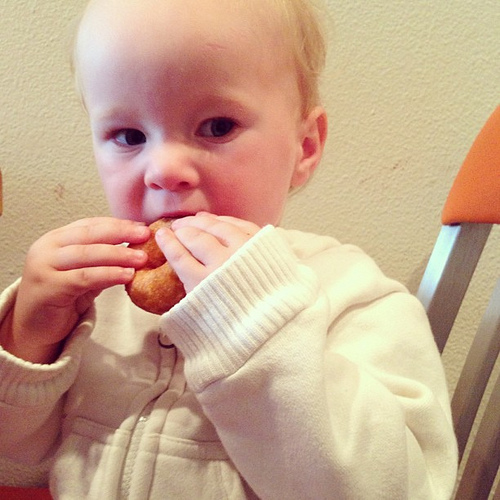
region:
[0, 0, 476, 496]
Baby eating a donut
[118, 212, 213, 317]
Donut is brown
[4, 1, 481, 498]
Baby wears a white sweater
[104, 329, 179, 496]
Zipper of sweater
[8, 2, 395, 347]
Baby is blonde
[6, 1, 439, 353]
Baby is looking to the wright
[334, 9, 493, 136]
Wall is paint tan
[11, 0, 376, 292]
Baby is bold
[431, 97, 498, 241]
Orange stuff on right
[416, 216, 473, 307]
Window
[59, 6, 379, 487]
toddler eating a doughnut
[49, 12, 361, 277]
baby girls face with blonde hair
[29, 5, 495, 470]
young girl eating a snack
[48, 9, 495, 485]
little girl sitting in a chair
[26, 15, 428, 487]
toddler wearing a zip up sweater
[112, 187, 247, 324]
donut in small hands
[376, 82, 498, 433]
chair with orange back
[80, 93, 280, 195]
big brown eyes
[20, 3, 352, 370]
small girl enjoying a snack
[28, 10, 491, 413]
tan wall with food on it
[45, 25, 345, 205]
toddler with dark eyes and pale hair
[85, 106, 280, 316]
child eating a small doughnut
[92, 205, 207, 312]
hand holding doughnut to face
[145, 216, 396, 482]
ribbed cuff on edge of sleeve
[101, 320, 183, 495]
white zipper in front of jacket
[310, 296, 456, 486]
fabric folds on the sleeve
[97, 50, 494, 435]
chair to the child's side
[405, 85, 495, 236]
orange fabric on top of chair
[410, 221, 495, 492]
metal bars on back of chair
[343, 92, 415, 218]
white wall with dark marks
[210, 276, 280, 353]
sleeve of a sweater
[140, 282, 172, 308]
part of a doughnut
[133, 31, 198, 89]
head of a baby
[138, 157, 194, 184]
nose of a baby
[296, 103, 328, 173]
left ear of a baby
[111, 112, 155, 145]
right eye of the baby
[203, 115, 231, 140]
left eye of the baby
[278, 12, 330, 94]
hair of the baby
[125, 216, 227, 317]
crossaint is brown and eaten